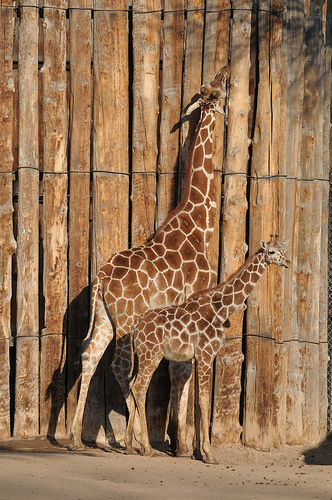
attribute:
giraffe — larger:
[58, 72, 232, 435]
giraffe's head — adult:
[186, 75, 244, 119]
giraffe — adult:
[87, 64, 249, 406]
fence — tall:
[5, 18, 112, 264]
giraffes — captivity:
[67, 65, 270, 465]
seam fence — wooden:
[10, 160, 331, 200]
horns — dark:
[191, 76, 228, 104]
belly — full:
[163, 350, 192, 363]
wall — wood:
[1, 1, 320, 444]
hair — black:
[126, 243, 293, 460]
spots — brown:
[197, 300, 216, 321]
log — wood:
[10, 0, 40, 440]